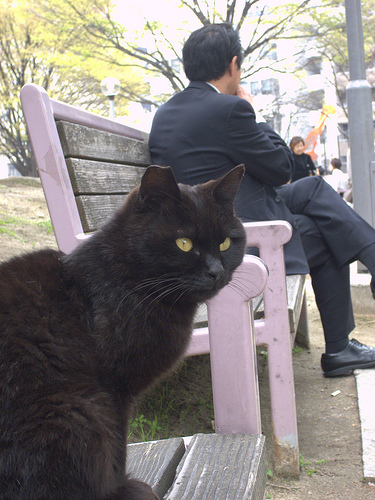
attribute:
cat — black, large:
[0, 160, 246, 497]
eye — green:
[173, 237, 196, 254]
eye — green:
[218, 235, 233, 253]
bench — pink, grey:
[20, 79, 309, 472]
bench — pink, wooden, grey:
[0, 253, 267, 499]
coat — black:
[290, 153, 320, 178]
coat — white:
[326, 171, 346, 193]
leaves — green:
[43, 38, 130, 77]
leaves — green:
[328, 22, 343, 65]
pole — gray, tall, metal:
[344, 5, 374, 274]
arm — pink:
[241, 222, 293, 243]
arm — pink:
[239, 257, 268, 302]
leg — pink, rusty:
[268, 335, 299, 481]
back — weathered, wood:
[18, 89, 156, 227]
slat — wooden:
[183, 435, 263, 499]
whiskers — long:
[114, 275, 276, 316]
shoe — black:
[322, 341, 374, 375]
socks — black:
[326, 345, 346, 353]